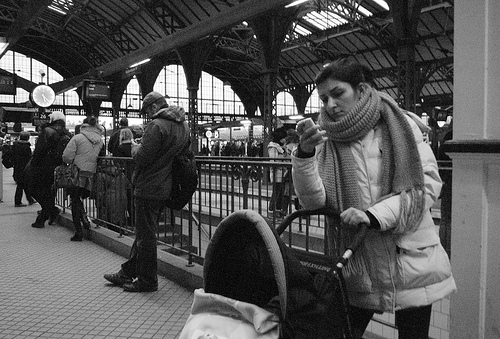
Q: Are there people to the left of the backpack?
A: Yes, there is a person to the left of the backpack.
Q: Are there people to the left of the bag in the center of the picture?
A: Yes, there is a person to the left of the backpack.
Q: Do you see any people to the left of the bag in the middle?
A: Yes, there is a person to the left of the backpack.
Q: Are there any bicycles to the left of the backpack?
A: No, there is a person to the left of the backpack.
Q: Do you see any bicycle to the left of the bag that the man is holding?
A: No, there is a person to the left of the backpack.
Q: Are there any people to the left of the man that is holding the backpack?
A: Yes, there is a person to the left of the man.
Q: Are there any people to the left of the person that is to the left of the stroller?
A: Yes, there is a person to the left of the man.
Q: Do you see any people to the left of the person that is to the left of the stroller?
A: Yes, there is a person to the left of the man.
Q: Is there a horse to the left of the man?
A: No, there is a person to the left of the man.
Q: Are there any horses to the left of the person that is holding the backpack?
A: No, there is a person to the left of the man.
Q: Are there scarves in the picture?
A: Yes, there is a scarf.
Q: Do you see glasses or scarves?
A: Yes, there is a scarf.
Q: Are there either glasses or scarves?
A: Yes, there is a scarf.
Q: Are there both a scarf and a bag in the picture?
A: Yes, there are both a scarf and a bag.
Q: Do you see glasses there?
A: No, there are no glasses.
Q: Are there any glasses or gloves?
A: No, there are no glasses or gloves.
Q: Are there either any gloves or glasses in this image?
A: No, there are no glasses or gloves.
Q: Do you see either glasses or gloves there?
A: No, there are no glasses or gloves.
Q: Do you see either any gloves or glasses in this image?
A: No, there are no glasses or gloves.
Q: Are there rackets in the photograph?
A: No, there are no rackets.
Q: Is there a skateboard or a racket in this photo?
A: No, there are no rackets or skateboards.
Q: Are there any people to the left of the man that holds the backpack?
A: Yes, there is a person to the left of the man.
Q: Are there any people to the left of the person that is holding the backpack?
A: Yes, there is a person to the left of the man.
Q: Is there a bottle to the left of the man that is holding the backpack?
A: No, there is a person to the left of the man.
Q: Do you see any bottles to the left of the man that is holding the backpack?
A: No, there is a person to the left of the man.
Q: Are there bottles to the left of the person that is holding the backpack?
A: No, there is a person to the left of the man.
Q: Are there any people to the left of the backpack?
A: Yes, there is a person to the left of the backpack.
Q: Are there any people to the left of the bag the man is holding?
A: Yes, there is a person to the left of the backpack.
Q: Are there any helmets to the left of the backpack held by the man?
A: No, there is a person to the left of the backpack.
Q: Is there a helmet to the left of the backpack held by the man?
A: No, there is a person to the left of the backpack.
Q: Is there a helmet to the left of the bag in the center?
A: No, there is a person to the left of the backpack.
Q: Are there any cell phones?
A: Yes, there is a cell phone.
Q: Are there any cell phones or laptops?
A: Yes, there is a cell phone.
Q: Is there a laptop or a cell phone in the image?
A: Yes, there is a cell phone.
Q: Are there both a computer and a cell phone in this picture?
A: No, there is a cell phone but no computers.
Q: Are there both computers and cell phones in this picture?
A: No, there is a cell phone but no computers.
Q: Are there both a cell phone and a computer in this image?
A: No, there is a cell phone but no computers.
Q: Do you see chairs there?
A: No, there are no chairs.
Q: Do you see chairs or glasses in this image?
A: No, there are no chairs or glasses.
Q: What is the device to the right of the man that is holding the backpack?
A: The device is a cell phone.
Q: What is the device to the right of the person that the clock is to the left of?
A: The device is a cell phone.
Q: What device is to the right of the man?
A: The device is a cell phone.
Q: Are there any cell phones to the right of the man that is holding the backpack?
A: Yes, there is a cell phone to the right of the man.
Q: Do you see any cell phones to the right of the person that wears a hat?
A: Yes, there is a cell phone to the right of the man.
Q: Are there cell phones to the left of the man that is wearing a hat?
A: No, the cell phone is to the right of the man.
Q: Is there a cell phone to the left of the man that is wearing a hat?
A: No, the cell phone is to the right of the man.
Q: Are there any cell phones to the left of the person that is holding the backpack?
A: No, the cell phone is to the right of the man.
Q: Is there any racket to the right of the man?
A: No, there is a cell phone to the right of the man.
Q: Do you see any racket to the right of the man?
A: No, there is a cell phone to the right of the man.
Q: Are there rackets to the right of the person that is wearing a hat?
A: No, there is a cell phone to the right of the man.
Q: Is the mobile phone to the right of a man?
A: Yes, the mobile phone is to the right of a man.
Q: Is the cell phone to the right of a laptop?
A: No, the cell phone is to the right of a man.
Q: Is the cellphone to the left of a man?
A: No, the cellphone is to the right of a man.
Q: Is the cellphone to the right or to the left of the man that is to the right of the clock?
A: The cellphone is to the right of the man.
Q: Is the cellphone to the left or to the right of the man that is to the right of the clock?
A: The cellphone is to the right of the man.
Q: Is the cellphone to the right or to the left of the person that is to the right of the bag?
A: The cellphone is to the right of the man.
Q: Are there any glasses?
A: No, there are no glasses.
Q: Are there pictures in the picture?
A: No, there are no pictures.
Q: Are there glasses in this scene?
A: No, there are no glasses.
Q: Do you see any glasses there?
A: No, there are no glasses.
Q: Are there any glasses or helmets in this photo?
A: No, there are no glasses or helmets.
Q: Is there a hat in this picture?
A: Yes, there is a hat.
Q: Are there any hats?
A: Yes, there is a hat.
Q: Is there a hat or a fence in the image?
A: Yes, there is a hat.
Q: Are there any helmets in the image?
A: No, there are no helmets.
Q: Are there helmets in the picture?
A: No, there are no helmets.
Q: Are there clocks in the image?
A: Yes, there is a clock.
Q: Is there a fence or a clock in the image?
A: Yes, there is a clock.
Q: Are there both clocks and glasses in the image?
A: No, there is a clock but no glasses.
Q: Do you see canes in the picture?
A: No, there are no canes.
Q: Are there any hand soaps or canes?
A: No, there are no canes or hand soaps.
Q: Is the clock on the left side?
A: Yes, the clock is on the left of the image.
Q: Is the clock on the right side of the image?
A: No, the clock is on the left of the image.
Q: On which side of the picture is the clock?
A: The clock is on the left of the image.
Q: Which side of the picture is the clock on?
A: The clock is on the left of the image.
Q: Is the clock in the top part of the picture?
A: Yes, the clock is in the top of the image.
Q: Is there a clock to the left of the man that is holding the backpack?
A: Yes, there is a clock to the left of the man.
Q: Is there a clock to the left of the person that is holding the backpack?
A: Yes, there is a clock to the left of the man.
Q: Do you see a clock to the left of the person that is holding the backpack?
A: Yes, there is a clock to the left of the man.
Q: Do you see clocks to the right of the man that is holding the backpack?
A: No, the clock is to the left of the man.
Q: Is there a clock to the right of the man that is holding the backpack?
A: No, the clock is to the left of the man.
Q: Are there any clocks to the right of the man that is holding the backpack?
A: No, the clock is to the left of the man.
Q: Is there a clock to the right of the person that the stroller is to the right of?
A: No, the clock is to the left of the man.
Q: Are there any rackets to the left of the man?
A: No, there is a clock to the left of the man.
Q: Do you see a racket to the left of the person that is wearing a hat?
A: No, there is a clock to the left of the man.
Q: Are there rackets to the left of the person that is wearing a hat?
A: No, there is a clock to the left of the man.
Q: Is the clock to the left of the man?
A: Yes, the clock is to the left of the man.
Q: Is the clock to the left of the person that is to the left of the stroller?
A: Yes, the clock is to the left of the man.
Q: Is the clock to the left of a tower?
A: No, the clock is to the left of the man.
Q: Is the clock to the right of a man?
A: No, the clock is to the left of a man.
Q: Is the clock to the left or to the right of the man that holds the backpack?
A: The clock is to the left of the man.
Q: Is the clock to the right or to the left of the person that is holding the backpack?
A: The clock is to the left of the man.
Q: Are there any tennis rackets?
A: No, there are no tennis rackets.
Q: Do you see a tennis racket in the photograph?
A: No, there are no rackets.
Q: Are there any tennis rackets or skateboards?
A: No, there are no tennis rackets or skateboards.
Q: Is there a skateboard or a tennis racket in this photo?
A: No, there are no rackets or skateboards.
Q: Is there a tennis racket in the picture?
A: No, there are no rackets.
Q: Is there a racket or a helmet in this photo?
A: No, there are no rackets or helmets.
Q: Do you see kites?
A: No, there are no kites.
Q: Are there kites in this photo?
A: No, there are no kites.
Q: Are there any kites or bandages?
A: No, there are no kites or bandages.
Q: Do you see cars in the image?
A: No, there are no cars.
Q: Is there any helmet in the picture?
A: No, there are no helmets.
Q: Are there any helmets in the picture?
A: No, there are no helmets.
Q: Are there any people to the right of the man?
A: Yes, there is a person to the right of the man.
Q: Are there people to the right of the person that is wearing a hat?
A: Yes, there is a person to the right of the man.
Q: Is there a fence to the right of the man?
A: No, there is a person to the right of the man.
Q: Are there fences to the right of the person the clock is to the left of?
A: No, there is a person to the right of the man.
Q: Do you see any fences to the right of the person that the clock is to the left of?
A: No, there is a person to the right of the man.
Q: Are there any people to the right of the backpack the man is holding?
A: Yes, there is a person to the right of the backpack.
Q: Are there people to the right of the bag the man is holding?
A: Yes, there is a person to the right of the backpack.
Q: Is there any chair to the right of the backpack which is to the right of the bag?
A: No, there is a person to the right of the backpack.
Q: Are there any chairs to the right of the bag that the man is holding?
A: No, there is a person to the right of the backpack.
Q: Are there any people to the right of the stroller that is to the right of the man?
A: Yes, there is a person to the right of the stroller.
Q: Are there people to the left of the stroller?
A: No, the person is to the right of the stroller.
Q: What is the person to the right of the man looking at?
A: The person is looking at the cell phone.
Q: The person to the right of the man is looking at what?
A: The person is looking at the cell phone.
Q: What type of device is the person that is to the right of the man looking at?
A: The person is looking at the mobile phone.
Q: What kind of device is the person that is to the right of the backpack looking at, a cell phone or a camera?
A: The person is looking at a cell phone.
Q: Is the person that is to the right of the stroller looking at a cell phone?
A: Yes, the person is looking at a cell phone.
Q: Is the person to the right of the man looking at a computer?
A: No, the person is looking at a cell phone.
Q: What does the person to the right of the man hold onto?
A: The person holds onto the stroller.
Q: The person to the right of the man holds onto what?
A: The person holds onto the stroller.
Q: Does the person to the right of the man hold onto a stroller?
A: Yes, the person holds onto a stroller.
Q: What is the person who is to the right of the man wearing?
A: The person is wearing a scarf.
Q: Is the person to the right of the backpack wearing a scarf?
A: Yes, the person is wearing a scarf.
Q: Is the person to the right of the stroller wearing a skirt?
A: No, the person is wearing a scarf.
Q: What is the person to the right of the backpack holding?
A: The person is holding the cell phone.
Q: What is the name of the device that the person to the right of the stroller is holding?
A: The device is a cell phone.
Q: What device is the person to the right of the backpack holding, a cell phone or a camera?
A: The person is holding a cell phone.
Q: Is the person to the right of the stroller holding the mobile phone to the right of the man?
A: Yes, the person is holding the cellphone.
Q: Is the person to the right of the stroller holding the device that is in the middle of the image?
A: Yes, the person is holding the cellphone.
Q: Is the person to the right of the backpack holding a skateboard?
A: No, the person is holding the cellphone.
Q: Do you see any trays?
A: No, there are no trays.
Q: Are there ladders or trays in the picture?
A: No, there are no trays or ladders.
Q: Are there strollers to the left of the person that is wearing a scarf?
A: Yes, there is a stroller to the left of the person.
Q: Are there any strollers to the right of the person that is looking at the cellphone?
A: No, the stroller is to the left of the person.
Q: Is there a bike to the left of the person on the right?
A: No, there is a stroller to the left of the person.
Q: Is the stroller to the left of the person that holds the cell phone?
A: Yes, the stroller is to the left of the person.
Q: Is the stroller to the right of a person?
A: No, the stroller is to the left of a person.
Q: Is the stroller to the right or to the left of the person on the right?
A: The stroller is to the left of the person.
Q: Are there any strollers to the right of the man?
A: Yes, there is a stroller to the right of the man.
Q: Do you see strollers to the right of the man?
A: Yes, there is a stroller to the right of the man.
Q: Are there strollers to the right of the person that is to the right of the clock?
A: Yes, there is a stroller to the right of the man.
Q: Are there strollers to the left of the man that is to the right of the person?
A: No, the stroller is to the right of the man.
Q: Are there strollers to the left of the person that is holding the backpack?
A: No, the stroller is to the right of the man.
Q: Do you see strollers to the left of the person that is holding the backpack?
A: No, the stroller is to the right of the man.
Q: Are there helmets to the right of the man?
A: No, there is a stroller to the right of the man.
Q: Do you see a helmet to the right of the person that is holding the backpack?
A: No, there is a stroller to the right of the man.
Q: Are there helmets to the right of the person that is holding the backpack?
A: No, there is a stroller to the right of the man.